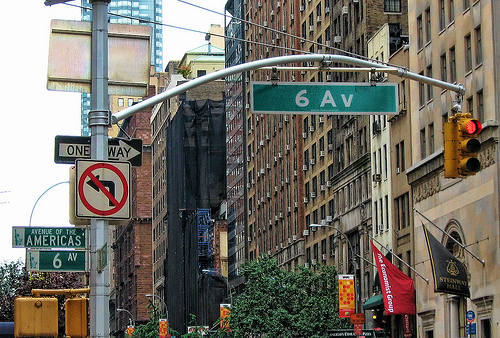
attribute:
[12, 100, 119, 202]
sky — clear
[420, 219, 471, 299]
flag — black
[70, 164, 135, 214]
sign — red, black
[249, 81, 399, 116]
sign — green, white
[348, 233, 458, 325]
flag — black, golden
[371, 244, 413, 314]
flag — red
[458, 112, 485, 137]
traffic light — red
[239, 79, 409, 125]
sign — red, white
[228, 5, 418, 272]
building — brown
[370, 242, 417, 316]
flag — gold, black, red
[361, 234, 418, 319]
flag — red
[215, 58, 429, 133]
sign — green, white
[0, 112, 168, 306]
signs — yellow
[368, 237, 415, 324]
flag — red, white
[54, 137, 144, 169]
sign — black, white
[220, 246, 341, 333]
trees — large, green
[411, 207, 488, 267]
pole — metal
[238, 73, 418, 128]
sign — green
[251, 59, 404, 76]
pole — grey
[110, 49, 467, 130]
pole — grey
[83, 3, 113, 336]
pole — grey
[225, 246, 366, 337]
tree — green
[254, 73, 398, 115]
street sign — green, white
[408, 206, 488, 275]
flag pole — metal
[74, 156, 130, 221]
sign — red, white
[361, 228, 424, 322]
flag — Red 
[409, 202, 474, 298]
flag — black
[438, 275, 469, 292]
lettering — gold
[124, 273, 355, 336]
banners — red, orange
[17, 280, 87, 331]
light — yellow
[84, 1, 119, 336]
pole — metal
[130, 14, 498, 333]
buildings — large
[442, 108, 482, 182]
light — red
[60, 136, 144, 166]
arrow — white